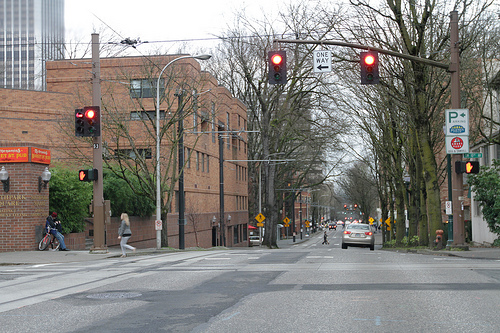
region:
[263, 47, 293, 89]
a black bank of traffic lights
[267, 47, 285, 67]
a red traffic light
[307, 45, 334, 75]
a white sign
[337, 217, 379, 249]
a gray car on the road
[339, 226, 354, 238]
a red tail light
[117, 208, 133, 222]
the head of a person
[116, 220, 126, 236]
the arm of a person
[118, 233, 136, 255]
the legs of a person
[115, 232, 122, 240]
the hand of a person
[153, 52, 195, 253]
a gray metal light post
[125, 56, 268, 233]
Brown colored brick building.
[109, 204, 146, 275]
Woman with blonde hair walking.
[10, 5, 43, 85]
Metal building in background.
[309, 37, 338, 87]
Black and white street sign.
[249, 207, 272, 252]
Yellow cross walking sign.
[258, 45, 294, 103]
Traffic light showing red.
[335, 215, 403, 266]
Silver colored car on street.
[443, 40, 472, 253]
Brown colored metal pole.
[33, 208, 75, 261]
Man sitting on bicycle.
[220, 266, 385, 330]
Black and grey asphalt.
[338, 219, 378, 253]
Silver car driving on road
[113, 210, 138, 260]
Woman crossing the street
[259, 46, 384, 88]
Traffic lights are red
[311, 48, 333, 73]
White one way sign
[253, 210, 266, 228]
Yellow walking sign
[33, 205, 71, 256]
Man sitting on bicycle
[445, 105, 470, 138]
White and green parking sign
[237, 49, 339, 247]
Tree that is bare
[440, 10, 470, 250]
Street light pole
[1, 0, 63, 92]
Tall silver building in the background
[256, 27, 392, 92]
Two traffic lights above the street.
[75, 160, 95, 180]
The red hand is visible on the light.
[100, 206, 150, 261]
A person is walking.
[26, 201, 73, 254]
Person with a bicycle.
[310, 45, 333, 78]
A one way sign.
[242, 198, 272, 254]
A yellow street sign.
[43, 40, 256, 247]
The building is reddish-borwn.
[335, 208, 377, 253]
A car on the street.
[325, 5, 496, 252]
The tree does not have any leaves.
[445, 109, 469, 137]
A sign with a P on it.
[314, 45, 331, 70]
one way sign above a street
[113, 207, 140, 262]
blonde woman crossing the street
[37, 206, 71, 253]
person leaning with a bike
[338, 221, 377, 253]
silver car driving down the road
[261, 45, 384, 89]
two red traffic lights hanging over the road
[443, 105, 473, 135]
sign showing parking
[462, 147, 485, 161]
green street sign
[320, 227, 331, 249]
person crossing the street in the distance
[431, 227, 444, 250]
old red fire hydrant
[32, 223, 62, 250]
person's red bike